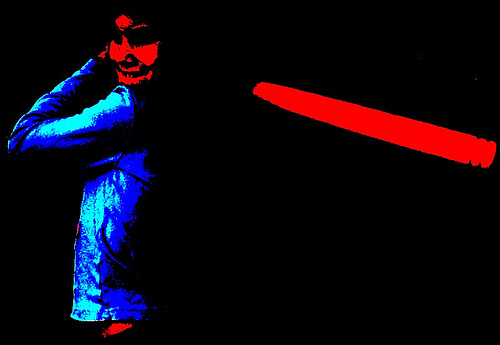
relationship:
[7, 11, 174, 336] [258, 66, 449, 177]
body stands up with bat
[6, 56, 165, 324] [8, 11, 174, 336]
shirt on body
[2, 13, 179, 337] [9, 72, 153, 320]
woman wearing shirt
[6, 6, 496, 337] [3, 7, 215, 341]
area around woman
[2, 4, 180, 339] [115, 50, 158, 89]
woman biting lip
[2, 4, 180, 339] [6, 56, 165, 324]
woman in shirt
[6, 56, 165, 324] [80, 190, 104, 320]
shirt has lights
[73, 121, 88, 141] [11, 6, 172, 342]
elbow of person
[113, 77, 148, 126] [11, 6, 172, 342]
shoulder of person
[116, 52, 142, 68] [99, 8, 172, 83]
nose on face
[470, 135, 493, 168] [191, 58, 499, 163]
end of bat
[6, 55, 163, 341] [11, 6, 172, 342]
shirt on person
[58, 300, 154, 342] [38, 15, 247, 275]
belt on person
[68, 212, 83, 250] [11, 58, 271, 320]
button on jacket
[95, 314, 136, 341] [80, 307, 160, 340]
part on waist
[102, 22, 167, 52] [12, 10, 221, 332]
eyes on person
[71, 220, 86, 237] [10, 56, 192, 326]
bit on jacket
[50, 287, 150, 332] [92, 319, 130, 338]
stomach under shirt